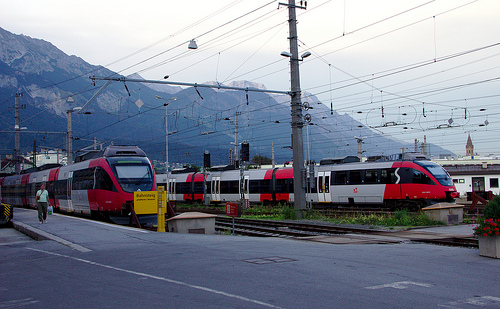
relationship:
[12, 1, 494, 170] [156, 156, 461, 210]
wires above train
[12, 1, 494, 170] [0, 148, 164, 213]
wires above train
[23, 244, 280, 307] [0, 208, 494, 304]
white line on ground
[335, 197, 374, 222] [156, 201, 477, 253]
grass next to tracks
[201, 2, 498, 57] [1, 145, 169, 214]
wires connect to trains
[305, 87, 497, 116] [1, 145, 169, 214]
wires connect to trains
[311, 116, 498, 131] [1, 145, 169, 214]
wires connect to trains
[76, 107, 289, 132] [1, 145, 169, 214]
wires connect to trains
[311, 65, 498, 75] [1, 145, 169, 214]
wires connect to trains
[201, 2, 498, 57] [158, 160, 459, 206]
wires connect to trains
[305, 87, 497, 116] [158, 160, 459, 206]
wires connect to trains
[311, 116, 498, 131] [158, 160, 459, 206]
wires connect to trains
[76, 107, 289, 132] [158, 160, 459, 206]
wires connect to trains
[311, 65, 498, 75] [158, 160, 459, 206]
wires connect to trains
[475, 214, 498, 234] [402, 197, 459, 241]
flowers in planter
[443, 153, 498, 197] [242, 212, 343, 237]
building beside tracks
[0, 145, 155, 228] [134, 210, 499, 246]
train on track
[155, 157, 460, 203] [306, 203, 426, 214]
train on track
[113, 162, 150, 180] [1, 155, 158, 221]
window on train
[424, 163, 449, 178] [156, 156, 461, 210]
window on train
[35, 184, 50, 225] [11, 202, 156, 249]
person walking on platform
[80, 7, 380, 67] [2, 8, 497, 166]
clouds in sky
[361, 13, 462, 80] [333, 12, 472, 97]
clouds in sky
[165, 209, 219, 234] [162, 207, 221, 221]
sunken structure has brown roof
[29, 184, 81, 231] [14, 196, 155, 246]
person walking on sidewalk